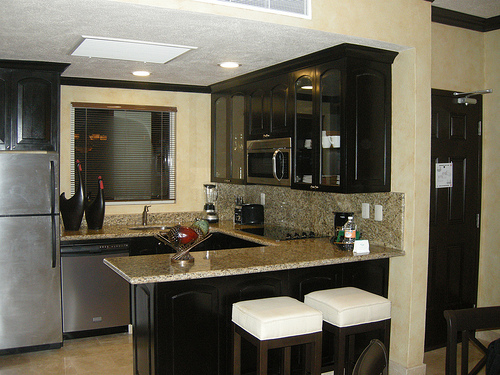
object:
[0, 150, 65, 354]
fridge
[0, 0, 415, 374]
kitchen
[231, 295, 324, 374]
bar stool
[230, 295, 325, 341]
cushion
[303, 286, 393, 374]
bar stool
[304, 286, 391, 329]
cushion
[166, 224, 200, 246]
acorns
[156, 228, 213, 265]
stand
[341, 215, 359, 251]
water bottle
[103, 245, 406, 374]
counter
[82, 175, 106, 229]
hens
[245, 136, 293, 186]
microwave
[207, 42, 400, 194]
cabinets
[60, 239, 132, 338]
dishwasher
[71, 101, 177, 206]
window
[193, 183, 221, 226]
blender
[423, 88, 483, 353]
door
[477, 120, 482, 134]
door hinge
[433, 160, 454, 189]
sign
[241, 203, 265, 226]
toaster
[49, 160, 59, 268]
handles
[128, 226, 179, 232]
sink